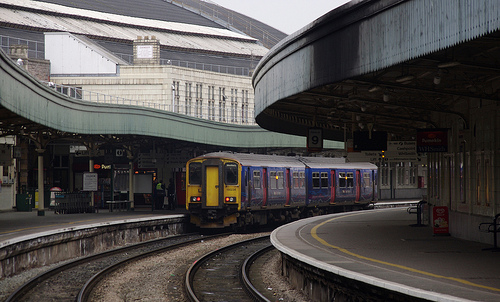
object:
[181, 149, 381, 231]
train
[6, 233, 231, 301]
track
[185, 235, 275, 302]
track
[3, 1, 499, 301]
station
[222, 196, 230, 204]
lights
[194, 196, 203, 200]
lights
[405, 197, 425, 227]
bench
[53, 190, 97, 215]
bench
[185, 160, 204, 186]
window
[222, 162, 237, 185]
window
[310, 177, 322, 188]
window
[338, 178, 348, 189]
window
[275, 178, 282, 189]
window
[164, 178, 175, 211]
person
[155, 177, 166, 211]
person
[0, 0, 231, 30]
roof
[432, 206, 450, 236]
posterboard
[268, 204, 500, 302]
walkway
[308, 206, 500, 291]
line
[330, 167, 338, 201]
door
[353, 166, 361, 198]
door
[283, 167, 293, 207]
door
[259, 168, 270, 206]
door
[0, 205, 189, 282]
platform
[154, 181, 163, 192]
vest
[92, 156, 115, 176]
sign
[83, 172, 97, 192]
sign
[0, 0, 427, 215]
building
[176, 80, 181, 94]
window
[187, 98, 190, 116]
window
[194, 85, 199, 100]
window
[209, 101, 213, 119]
window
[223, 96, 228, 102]
window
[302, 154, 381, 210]
rear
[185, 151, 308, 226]
front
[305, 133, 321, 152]
sign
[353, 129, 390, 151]
sign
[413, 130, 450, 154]
sign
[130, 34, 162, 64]
chimney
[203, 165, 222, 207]
door